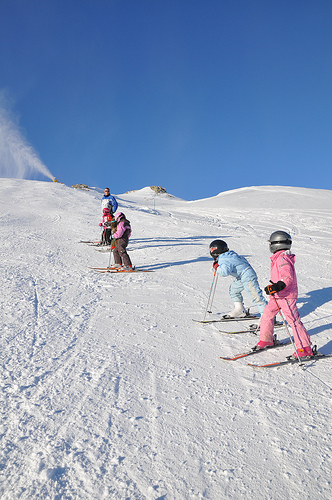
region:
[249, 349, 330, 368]
the long snow covered ski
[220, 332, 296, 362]
the long snow covered ski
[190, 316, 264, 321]
the long snow covered ski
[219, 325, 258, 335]
the long snow covered ski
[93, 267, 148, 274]
the long snow covered ski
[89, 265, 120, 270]
the long snow covered ski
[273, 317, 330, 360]
the shadow of the child skier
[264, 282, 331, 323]
the shadow of the child skier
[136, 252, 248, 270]
the shadow of the child skier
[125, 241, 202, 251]
the shadow of the child skier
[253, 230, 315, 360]
skier wearing pink snow pants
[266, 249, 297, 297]
pink jacket above snow pants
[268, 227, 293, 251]
skier wearing a gray helmet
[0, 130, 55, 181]
snow blowing against the sky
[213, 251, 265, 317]
skier wearing a blue snowsuit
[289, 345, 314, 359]
pink boots on top of skis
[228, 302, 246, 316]
white boot on top of ski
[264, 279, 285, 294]
black gloves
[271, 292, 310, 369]
skier holding a ski pole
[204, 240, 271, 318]
skier next to skier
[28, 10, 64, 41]
white clouds in blue sky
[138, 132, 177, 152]
white clouds in blue sky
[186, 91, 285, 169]
white clouds in blue sky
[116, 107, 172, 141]
white clouds in blue sky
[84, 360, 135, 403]
white snow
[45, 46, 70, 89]
white clouds in blue sky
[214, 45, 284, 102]
white clouds in blue sky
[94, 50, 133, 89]
white clouds in blue sky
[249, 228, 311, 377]
girl skier in snow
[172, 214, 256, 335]
girl skier in snow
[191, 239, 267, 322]
Boy wearing blue ski suit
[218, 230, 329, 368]
Girl wearing pink ski suit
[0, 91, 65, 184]
Machine blowing snow in the air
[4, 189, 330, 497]
Packed down snow on mountain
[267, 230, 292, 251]
Silver helmet on girl's head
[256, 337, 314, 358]
Pink snowboots on girl's feet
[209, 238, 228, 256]
Black helmet on boy's head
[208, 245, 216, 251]
Red logo on black helmet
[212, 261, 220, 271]
Black and red glove on boy's hand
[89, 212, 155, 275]
Girl in pink jacket standing on skis in snow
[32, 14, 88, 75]
white clouds in blue sky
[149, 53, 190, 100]
white clouds in blue sky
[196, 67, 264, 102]
white clouds in blue sky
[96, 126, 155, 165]
white clouds in blue sky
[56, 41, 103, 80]
white clouds in blue sky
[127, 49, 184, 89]
white clouds in blue sky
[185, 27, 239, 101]
white clouds in blue sky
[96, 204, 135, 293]
female skier in white snow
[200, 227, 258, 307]
female skier in white snow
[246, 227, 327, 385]
female skier in white snow